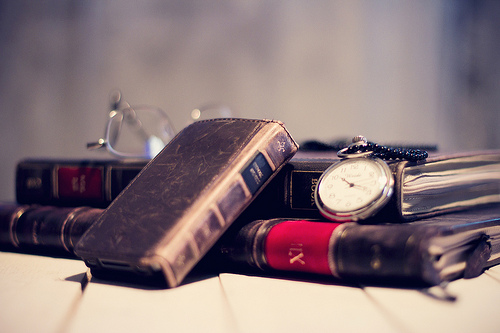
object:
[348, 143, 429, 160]
rope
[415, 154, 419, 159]
black bead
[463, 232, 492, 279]
ribbon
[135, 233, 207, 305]
part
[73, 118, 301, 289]
bible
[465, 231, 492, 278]
book mark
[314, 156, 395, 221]
clock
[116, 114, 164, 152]
glasses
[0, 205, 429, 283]
edge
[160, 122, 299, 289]
edge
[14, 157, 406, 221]
edge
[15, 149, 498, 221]
book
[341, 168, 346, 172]
numbers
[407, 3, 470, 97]
grey color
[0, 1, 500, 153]
background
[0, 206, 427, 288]
roun spine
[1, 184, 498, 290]
antique book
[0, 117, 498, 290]
library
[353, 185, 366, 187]
clock hand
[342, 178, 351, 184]
clock hand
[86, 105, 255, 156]
eye glass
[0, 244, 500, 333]
table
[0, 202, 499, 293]
book jacket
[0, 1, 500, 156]
wall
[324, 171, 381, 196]
color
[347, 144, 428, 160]
band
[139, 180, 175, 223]
leather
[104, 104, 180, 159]
frames